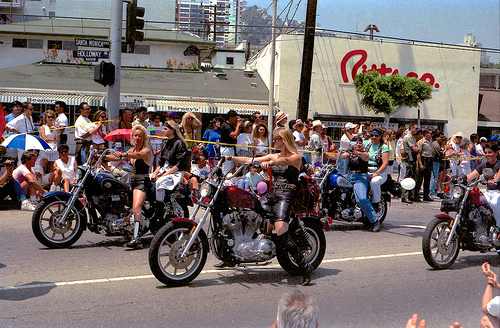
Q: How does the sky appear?
A: Clear.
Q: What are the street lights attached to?
A: Metal pole.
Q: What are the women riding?
A: Motorcycles.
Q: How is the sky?
A: Overcast.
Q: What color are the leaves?
A: Green.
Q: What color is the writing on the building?
A: Red.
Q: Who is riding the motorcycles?
A: Women.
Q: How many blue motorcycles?
A: Two.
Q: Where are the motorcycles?
A: On the road.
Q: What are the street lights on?
A: Poles.